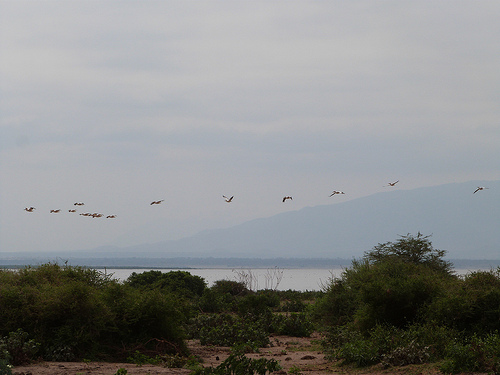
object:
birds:
[7, 166, 491, 221]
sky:
[0, 2, 500, 164]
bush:
[0, 231, 500, 344]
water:
[90, 266, 343, 290]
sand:
[257, 335, 327, 374]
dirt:
[4, 327, 500, 374]